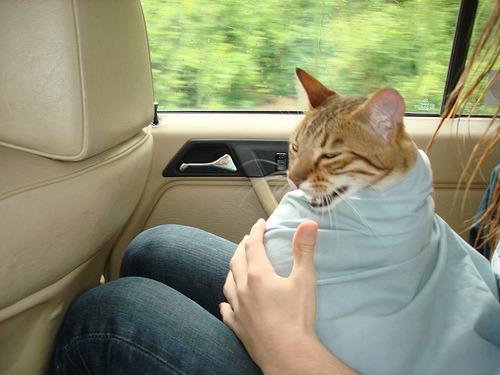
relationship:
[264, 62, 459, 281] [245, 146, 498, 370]
cat wrapped blanket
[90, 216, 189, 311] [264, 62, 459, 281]
knees next to cat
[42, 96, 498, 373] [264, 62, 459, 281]
girl holding cat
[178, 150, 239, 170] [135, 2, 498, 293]
handle on car door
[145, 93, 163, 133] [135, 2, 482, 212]
lock on car door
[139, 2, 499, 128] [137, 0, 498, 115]
greenery passing by window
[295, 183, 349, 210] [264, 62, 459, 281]
mouth on cat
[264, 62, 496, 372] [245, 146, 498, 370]
cat wrapped in blanket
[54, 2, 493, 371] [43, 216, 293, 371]
person wearing jeans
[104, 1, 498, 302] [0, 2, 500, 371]
door on car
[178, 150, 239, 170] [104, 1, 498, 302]
handle on door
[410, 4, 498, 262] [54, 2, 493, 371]
hair on person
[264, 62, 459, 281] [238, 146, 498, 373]
cat wrapped in sheet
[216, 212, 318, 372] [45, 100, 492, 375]
hand on person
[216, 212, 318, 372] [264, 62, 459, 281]
hand holding cat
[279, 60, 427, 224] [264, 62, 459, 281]
head on cat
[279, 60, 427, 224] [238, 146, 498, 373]
head above sheet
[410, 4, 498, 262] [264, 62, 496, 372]
hair near cat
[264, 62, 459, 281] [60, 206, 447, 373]
cat held on lap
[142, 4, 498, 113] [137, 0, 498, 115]
foliage blurred through window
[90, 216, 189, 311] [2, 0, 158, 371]
knees close to seat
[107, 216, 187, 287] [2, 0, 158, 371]
knees close to seat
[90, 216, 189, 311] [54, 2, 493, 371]
knees on person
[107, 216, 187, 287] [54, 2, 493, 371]
knees on person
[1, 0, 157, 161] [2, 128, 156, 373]
headrest on seat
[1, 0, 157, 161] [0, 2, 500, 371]
headrest in car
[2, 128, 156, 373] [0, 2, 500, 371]
seat in car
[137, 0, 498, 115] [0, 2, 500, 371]
window in car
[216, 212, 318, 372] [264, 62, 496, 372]
hand holding cat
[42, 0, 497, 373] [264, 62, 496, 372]
girl holding cat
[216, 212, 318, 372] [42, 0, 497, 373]
hand on girl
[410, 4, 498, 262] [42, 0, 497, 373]
hair on girl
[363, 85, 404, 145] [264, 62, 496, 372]
ear on cat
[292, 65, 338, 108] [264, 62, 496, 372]
ear on cat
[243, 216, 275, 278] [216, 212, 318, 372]
finger on hand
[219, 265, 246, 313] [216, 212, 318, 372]
finger on hand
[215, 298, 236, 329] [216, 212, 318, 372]
finger on hand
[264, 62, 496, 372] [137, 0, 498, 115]
cat beside window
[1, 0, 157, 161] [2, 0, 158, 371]
headrest on seat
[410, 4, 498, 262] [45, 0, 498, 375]
hair on passenger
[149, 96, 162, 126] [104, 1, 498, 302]
knob on door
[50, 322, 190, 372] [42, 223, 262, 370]
seam on dungarees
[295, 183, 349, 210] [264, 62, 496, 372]
mouth on cat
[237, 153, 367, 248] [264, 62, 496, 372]
whiskers on cat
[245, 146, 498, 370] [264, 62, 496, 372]
blanket wrapped around cat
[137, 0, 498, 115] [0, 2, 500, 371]
window on car